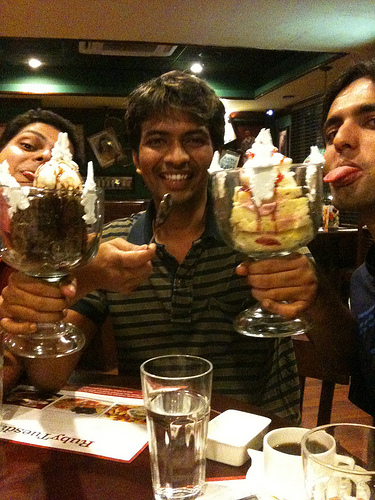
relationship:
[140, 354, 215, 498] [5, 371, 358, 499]
glass on table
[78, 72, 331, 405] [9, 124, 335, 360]
man holding ice cream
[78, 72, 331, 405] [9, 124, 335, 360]
man with ice cream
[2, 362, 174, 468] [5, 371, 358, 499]
mat on table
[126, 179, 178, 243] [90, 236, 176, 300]
spoon in hand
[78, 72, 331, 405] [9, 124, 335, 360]
man with h ice cream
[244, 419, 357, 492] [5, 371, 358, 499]
mug on table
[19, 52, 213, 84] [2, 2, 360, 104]
lights in ceiling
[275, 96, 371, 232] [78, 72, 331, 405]
window behind man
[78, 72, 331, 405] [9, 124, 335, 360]
man holding cold ice cream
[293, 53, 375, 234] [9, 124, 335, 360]
person licking ice cream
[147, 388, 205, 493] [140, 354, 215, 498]
water in glass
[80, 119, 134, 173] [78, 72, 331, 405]
picture behind man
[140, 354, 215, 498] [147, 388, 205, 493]
glass full of water